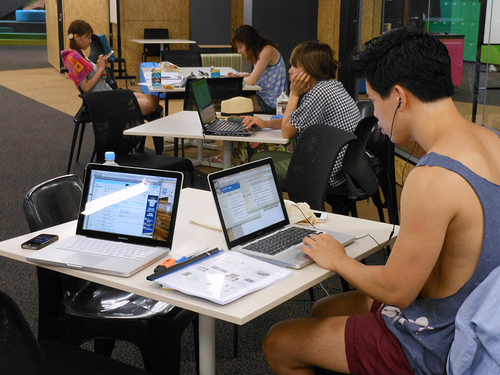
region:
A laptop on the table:
[23, 153, 189, 283]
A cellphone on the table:
[19, 229, 61, 251]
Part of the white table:
[243, 304, 253, 313]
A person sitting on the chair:
[260, 22, 499, 372]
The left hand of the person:
[298, 226, 352, 267]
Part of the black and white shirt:
[326, 98, 345, 120]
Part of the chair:
[37, 189, 57, 209]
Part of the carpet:
[11, 108, 48, 148]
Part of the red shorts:
[374, 337, 385, 364]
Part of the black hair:
[385, 42, 435, 70]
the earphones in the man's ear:
[292, 98, 416, 258]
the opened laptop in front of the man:
[207, 155, 354, 270]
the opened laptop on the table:
[25, 163, 182, 278]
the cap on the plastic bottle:
[105, 150, 115, 160]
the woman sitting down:
[61, 20, 166, 154]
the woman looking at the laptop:
[190, 38, 358, 186]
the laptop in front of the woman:
[190, 75, 255, 135]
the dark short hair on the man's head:
[352, 24, 453, 103]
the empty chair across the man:
[22, 170, 199, 373]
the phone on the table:
[20, 231, 59, 251]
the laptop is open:
[194, 141, 382, 301]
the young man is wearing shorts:
[294, 278, 414, 373]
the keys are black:
[243, 218, 336, 266]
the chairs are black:
[1, 157, 179, 351]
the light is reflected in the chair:
[77, 284, 149, 324]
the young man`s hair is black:
[337, 17, 454, 104]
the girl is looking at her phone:
[25, 0, 142, 91]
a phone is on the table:
[12, 222, 70, 257]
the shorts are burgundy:
[297, 300, 407, 371]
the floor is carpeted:
[7, 92, 67, 167]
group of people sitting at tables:
[40, 2, 489, 362]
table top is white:
[13, 120, 404, 360]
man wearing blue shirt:
[371, 130, 498, 353]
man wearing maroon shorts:
[324, 269, 427, 373]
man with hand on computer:
[254, 202, 358, 286]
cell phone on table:
[20, 206, 61, 270]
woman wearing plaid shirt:
[268, 62, 392, 174]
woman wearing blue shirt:
[240, 42, 295, 113]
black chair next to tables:
[239, 106, 365, 230]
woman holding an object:
[55, 15, 154, 130]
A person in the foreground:
[251, 22, 498, 373]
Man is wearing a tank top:
[315, 17, 497, 374]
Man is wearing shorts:
[328, 281, 431, 373]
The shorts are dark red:
[328, 284, 425, 372]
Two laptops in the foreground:
[22, 141, 364, 286]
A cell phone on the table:
[6, 225, 60, 265]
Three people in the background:
[45, 2, 365, 209]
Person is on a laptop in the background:
[173, 40, 358, 202]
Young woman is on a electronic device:
[46, 13, 165, 156]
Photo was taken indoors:
[2, 3, 497, 373]